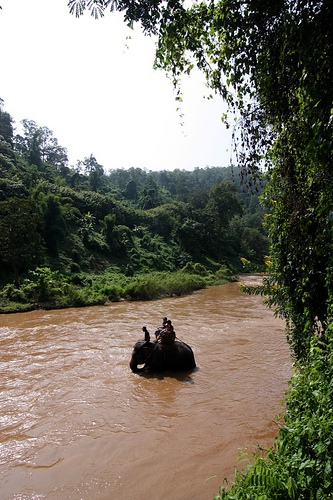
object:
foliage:
[212, 312, 332, 500]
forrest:
[0, 94, 273, 317]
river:
[0, 271, 325, 498]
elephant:
[128, 336, 196, 380]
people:
[140, 325, 152, 343]